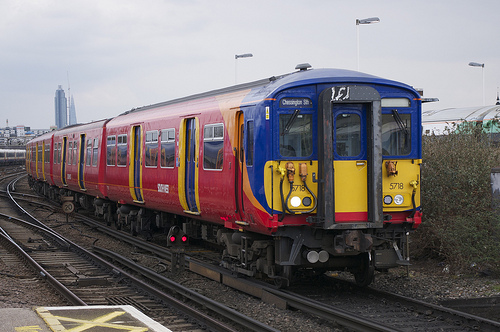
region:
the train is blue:
[14, 80, 430, 325]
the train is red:
[32, 89, 452, 274]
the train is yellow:
[17, 79, 442, 279]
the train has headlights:
[278, 189, 422, 213]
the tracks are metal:
[122, 260, 163, 297]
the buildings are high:
[49, 81, 81, 117]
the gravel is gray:
[209, 289, 265, 310]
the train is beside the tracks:
[29, 233, 132, 290]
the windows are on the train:
[142, 126, 180, 172]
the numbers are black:
[389, 180, 407, 194]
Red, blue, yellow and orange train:
[25, 61, 426, 273]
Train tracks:
[322, 287, 457, 324]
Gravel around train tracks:
[431, 272, 471, 293]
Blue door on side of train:
[173, 108, 208, 215]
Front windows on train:
[273, 102, 411, 162]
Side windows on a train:
[136, 125, 177, 165]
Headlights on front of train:
[280, 186, 427, 206]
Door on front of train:
[325, 101, 385, 221]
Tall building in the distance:
[36, 77, 91, 123]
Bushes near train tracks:
[425, 148, 482, 221]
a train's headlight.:
[283, 192, 306, 220]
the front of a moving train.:
[263, 65, 428, 228]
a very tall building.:
[53, 85, 75, 131]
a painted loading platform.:
[0, 300, 177, 330]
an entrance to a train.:
[176, 110, 201, 214]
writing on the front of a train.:
[272, 91, 312, 111]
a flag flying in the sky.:
[349, 12, 381, 77]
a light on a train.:
[180, 221, 197, 243]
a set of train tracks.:
[0, 161, 287, 327]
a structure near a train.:
[427, 101, 497, 133]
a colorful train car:
[25, 62, 440, 284]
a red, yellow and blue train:
[102, 59, 442, 284]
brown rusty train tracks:
[0, 163, 498, 330]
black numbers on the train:
[388, 179, 404, 192]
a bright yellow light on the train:
[290, 194, 302, 208]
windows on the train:
[19, 105, 413, 170]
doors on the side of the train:
[36, 103, 253, 213]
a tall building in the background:
[51, 79, 78, 130]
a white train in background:
[0, 147, 24, 169]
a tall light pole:
[351, 16, 381, 73]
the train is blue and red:
[101, 72, 426, 328]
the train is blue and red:
[13, 40, 353, 285]